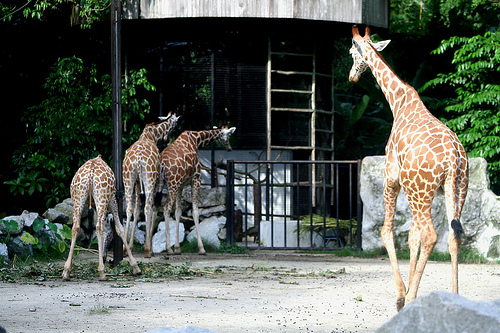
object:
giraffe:
[63, 153, 142, 281]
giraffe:
[349, 26, 469, 311]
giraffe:
[155, 126, 237, 254]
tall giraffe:
[121, 113, 184, 256]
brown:
[167, 150, 170, 154]